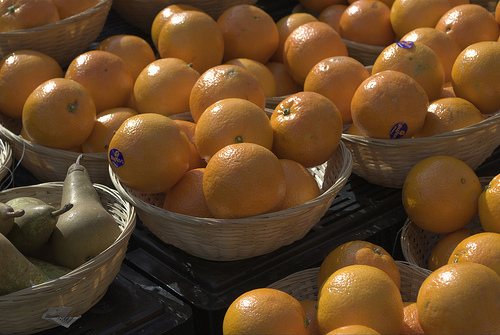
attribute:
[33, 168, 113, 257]
pear — gray, shiny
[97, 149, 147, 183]
sticker — blue, orange, produce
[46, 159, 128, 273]
pear — brown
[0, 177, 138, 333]
bowl — wicker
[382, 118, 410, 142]
sticker — blue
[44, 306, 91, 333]
label — white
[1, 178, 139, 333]
basket — wicker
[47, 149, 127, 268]
pear — green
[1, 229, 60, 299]
pear — green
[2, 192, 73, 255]
pear — green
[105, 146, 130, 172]
sticker — blue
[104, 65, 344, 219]
oranges — orange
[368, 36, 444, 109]
orange — not ripe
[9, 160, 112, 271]
pears — TOO RIPE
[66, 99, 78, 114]
stem — GREEN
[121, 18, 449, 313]
oranges — ROUND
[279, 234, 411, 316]
oranges — shiny, smooth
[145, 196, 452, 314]
crates — black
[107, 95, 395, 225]
oranges — shiny, fresh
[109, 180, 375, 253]
basket — wicker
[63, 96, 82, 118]
stem — orange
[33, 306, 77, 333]
sticker — stray, white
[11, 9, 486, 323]
oranges — in bowls, in the sunlight